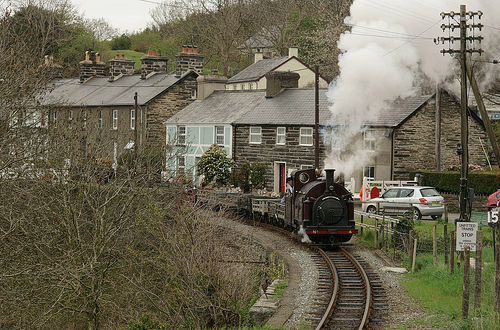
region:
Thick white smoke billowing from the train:
[335, 10, 432, 121]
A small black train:
[303, 182, 358, 244]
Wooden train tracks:
[322, 259, 385, 328]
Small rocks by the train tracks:
[287, 255, 324, 317]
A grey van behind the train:
[367, 186, 441, 216]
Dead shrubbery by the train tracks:
[42, 182, 189, 307]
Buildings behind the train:
[19, 50, 414, 165]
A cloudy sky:
[87, 1, 151, 32]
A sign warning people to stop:
[452, 220, 482, 260]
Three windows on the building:
[240, 124, 322, 154]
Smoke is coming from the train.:
[323, 6, 498, 253]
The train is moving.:
[189, 161, 364, 246]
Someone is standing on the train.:
[278, 175, 297, 230]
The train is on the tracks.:
[115, 158, 385, 329]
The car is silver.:
[365, 184, 446, 220]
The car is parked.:
[360, 183, 442, 220]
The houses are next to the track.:
[23, 60, 499, 217]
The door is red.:
[268, 157, 293, 198]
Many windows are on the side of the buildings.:
[25, 103, 393, 198]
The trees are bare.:
[8, 4, 262, 329]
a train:
[184, 150, 371, 250]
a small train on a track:
[183, 157, 363, 253]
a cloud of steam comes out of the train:
[296, 5, 443, 257]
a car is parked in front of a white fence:
[358, 175, 456, 214]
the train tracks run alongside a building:
[14, 154, 396, 329]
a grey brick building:
[228, 80, 487, 211]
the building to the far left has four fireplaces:
[35, 39, 221, 188]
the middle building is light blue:
[163, 70, 274, 202]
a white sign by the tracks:
[453, 214, 485, 257]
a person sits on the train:
[275, 161, 364, 253]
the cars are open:
[181, 173, 303, 228]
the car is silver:
[357, 180, 448, 231]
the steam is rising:
[319, 0, 498, 198]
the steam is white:
[316, 0, 499, 191]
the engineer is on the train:
[279, 173, 297, 201]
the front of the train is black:
[300, 160, 358, 245]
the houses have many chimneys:
[34, 40, 310, 113]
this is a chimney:
[261, 67, 304, 104]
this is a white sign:
[446, 215, 486, 257]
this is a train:
[183, 158, 362, 265]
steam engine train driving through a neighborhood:
[12, 19, 483, 320]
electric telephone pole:
[427, 4, 488, 242]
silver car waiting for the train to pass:
[359, 176, 455, 226]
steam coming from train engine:
[328, 13, 379, 183]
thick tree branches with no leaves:
[11, 155, 218, 315]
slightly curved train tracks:
[298, 244, 388, 329]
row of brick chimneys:
[71, 41, 205, 81]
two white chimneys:
[249, 41, 303, 60]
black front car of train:
[279, 164, 359, 246]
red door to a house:
[268, 155, 290, 199]